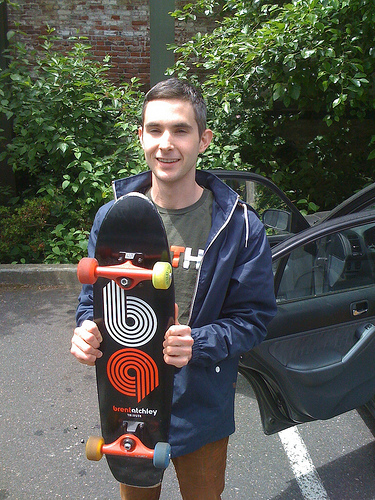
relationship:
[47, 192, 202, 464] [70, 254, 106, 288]
skateboard has wheel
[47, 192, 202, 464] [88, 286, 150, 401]
skateboard has design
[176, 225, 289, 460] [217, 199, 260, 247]
jacket has tie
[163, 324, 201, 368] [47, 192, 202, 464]
hands holding skateboard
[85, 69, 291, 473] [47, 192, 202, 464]
man with skateboard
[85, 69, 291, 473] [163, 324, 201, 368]
man has hands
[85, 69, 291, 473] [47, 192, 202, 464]
man holding skateboard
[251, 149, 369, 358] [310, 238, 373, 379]
car has door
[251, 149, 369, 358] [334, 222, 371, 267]
car has inside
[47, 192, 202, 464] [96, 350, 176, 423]
skateboard has bottom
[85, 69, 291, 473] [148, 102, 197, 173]
man has face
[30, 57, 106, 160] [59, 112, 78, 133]
tree has leaves